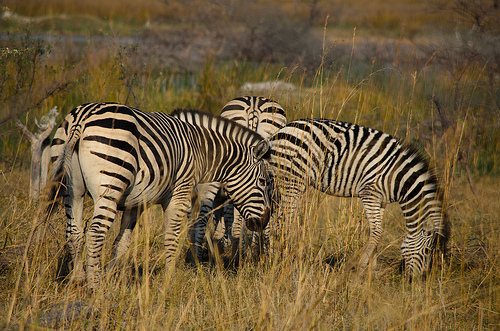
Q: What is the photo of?
A: Zebras.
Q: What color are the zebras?
A: Black and white.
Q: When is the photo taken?
A: Daytime.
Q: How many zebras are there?
A: Four.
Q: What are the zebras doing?
A: Eating.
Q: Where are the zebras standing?
A: In the grass.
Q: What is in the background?
A: Tree.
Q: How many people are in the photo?
A: None.